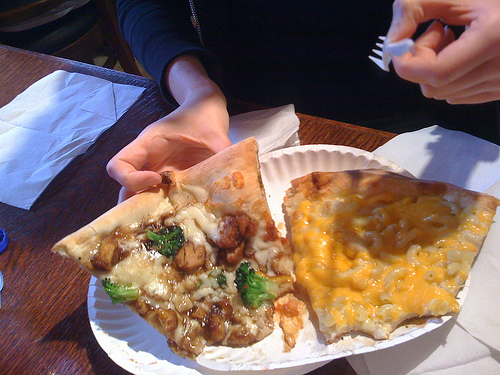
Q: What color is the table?
A: Brown.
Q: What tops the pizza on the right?
A: Macaroni and cheese.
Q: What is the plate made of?
A: Paper.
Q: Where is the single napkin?
A: To the left of the diner.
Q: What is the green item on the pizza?
A: Broccoli.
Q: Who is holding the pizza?
A: The diner.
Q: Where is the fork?
A: In the diner's hand.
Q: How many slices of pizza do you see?
A: Two.